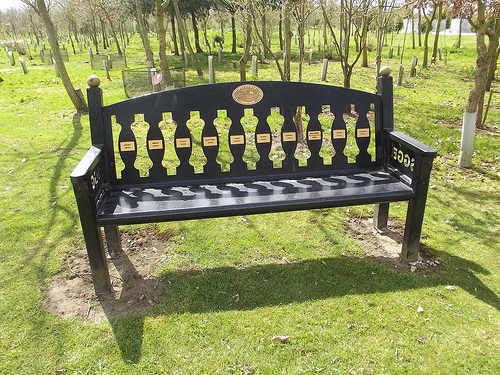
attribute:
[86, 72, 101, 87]
ball — wooden, decorative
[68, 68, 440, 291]
bench — black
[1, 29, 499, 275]
grass — brown, green, short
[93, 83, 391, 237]
bench — black, wooden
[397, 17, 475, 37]
fence — white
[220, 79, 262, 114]
symbol — gold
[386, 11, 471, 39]
buildings — white, distant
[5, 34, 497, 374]
grass — green, brown, short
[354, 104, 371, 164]
plaques — small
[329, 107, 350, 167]
plaques — small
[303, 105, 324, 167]
plaques — small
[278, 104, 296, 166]
plaques — small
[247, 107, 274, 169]
plaques — small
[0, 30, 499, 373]
green grass — short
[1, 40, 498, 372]
brown grass — short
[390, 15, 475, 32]
structure — wooden